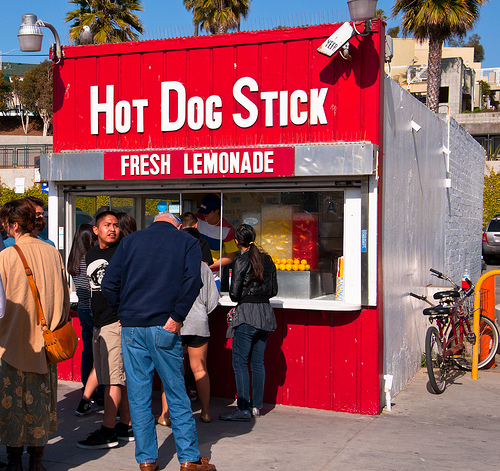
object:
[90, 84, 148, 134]
hot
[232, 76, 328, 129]
stick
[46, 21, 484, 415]
restaurant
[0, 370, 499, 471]
road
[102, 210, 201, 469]
person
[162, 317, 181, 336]
hands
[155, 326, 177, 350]
pocket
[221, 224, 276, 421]
girl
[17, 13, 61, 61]
light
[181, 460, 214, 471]
shoe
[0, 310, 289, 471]
shadow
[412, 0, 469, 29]
green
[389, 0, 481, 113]
tree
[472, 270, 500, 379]
pole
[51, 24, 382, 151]
sign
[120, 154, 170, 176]
fresh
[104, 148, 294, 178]
sign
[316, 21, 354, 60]
camera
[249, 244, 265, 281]
ponytail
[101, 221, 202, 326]
jacket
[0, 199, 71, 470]
woman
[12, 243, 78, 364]
bag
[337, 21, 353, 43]
white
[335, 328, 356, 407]
red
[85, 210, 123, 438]
man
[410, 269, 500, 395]
bike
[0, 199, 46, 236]
hair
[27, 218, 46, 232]
bun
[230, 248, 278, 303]
jacket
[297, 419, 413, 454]
gray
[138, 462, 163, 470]
shoes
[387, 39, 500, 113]
house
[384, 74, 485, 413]
wall